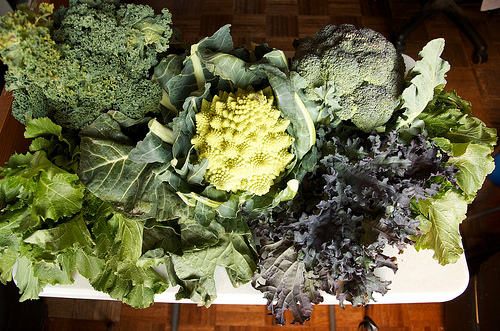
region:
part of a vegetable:
[443, 237, 446, 239]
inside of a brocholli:
[236, 119, 265, 174]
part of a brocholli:
[195, 134, 210, 148]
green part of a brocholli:
[122, 90, 128, 102]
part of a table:
[444, 296, 448, 306]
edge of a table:
[229, 294, 253, 306]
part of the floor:
[233, 312, 255, 322]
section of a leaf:
[55, 205, 122, 210]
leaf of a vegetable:
[65, 233, 75, 268]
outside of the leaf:
[427, 58, 453, 63]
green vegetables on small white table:
[16, 23, 456, 303]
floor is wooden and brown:
[416, 309, 451, 329]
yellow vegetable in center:
[200, 65, 310, 180]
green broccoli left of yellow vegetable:
[298, 21, 390, 118]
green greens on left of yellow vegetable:
[300, 35, 410, 105]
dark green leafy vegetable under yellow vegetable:
[301, 179, 421, 289]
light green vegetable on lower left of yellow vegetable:
[16, 166, 131, 313]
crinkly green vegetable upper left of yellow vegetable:
[11, 20, 161, 122]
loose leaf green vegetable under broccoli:
[416, 75, 491, 185]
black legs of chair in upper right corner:
[385, 3, 491, 74]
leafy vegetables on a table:
[0, 2, 495, 317]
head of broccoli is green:
[287, 10, 408, 130]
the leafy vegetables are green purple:
[1, 4, 498, 317]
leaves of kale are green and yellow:
[0, 0, 176, 143]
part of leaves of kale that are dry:
[5, 0, 66, 80]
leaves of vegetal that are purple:
[273, 142, 455, 318]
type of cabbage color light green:
[190, 81, 291, 197]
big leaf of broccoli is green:
[383, 30, 451, 130]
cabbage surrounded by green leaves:
[151, 65, 321, 213]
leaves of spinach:
[3, 186, 145, 318]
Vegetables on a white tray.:
[4, 3, 494, 307]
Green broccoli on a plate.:
[0, 1, 175, 138]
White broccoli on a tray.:
[76, 20, 319, 298]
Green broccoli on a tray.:
[287, 20, 454, 131]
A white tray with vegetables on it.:
[23, 233, 475, 308]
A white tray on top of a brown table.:
[22, 220, 474, 329]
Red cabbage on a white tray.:
[249, 128, 467, 327]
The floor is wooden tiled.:
[176, 4, 498, 108]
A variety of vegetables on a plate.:
[1, 0, 497, 305]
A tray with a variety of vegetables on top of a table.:
[1, 197, 480, 308]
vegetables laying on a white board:
[1, 9, 486, 314]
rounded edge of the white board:
[426, 265, 484, 307]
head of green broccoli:
[290, 13, 405, 141]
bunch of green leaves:
[3, 146, 158, 315]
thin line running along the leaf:
[38, 176, 74, 212]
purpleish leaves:
[243, 135, 445, 323]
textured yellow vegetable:
[186, 89, 291, 198]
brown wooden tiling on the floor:
[173, 3, 392, 58]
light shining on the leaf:
[401, 32, 453, 119]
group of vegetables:
[1, 6, 463, 324]